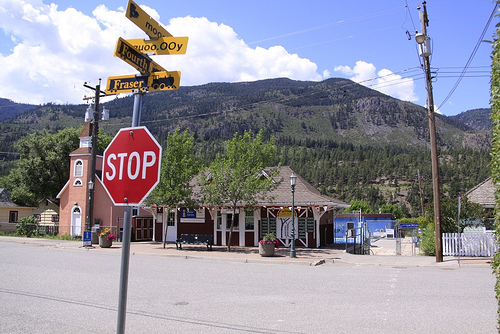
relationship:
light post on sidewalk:
[288, 170, 297, 258] [133, 248, 325, 267]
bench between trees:
[173, 233, 214, 250] [144, 124, 284, 254]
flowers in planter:
[101, 228, 116, 241] [98, 235, 110, 247]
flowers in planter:
[258, 232, 278, 245] [259, 243, 276, 258]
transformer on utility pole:
[416, 34, 433, 57] [414, 0, 443, 263]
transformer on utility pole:
[84, 105, 94, 124] [83, 77, 119, 230]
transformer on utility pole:
[100, 104, 110, 121] [83, 77, 119, 230]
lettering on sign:
[106, 151, 157, 181] [101, 125, 164, 206]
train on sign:
[151, 73, 174, 90] [106, 70, 180, 94]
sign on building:
[276, 216, 298, 240] [143, 166, 351, 248]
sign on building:
[179, 206, 207, 223] [143, 166, 351, 248]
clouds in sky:
[0, 0, 442, 114] [2, 0, 499, 116]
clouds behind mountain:
[0, 0, 442, 114] [2, 77, 491, 143]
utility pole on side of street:
[414, 0, 443, 263] [1, 235, 500, 331]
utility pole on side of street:
[83, 77, 119, 230] [1, 235, 500, 331]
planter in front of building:
[98, 235, 110, 247] [143, 166, 351, 248]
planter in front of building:
[259, 243, 276, 258] [143, 166, 351, 248]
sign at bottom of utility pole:
[82, 229, 93, 246] [83, 77, 119, 230]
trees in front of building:
[144, 124, 284, 254] [143, 166, 351, 248]